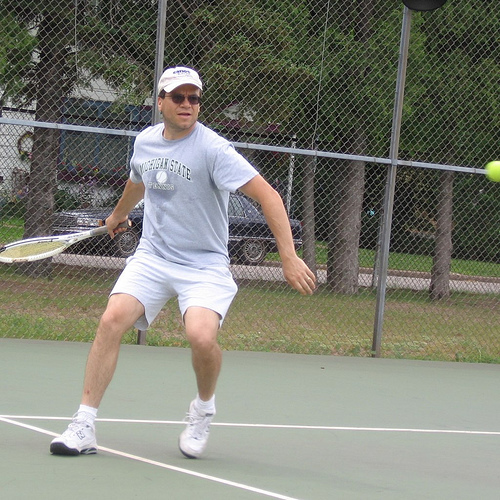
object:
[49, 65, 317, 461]
man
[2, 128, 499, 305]
tennis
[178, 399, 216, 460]
shoes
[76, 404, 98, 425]
socks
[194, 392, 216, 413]
socks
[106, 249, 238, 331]
shorts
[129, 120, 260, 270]
shirt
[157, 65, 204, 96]
hat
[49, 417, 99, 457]
tennis shoe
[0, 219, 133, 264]
tennis racket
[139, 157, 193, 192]
michigan state logo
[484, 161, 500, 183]
tennis ball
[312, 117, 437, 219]
air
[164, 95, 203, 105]
eye-glasses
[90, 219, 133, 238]
handle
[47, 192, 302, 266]
car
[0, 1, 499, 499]
tennis court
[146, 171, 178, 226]
sweat stains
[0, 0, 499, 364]
fence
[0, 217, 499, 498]
ground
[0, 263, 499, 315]
street side